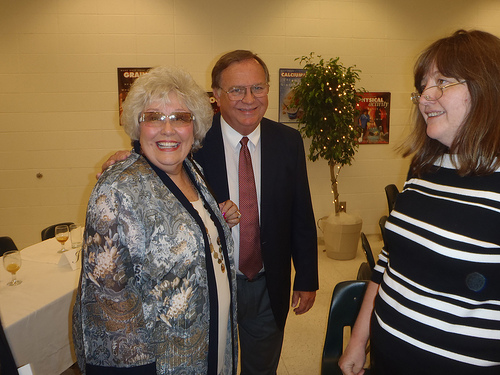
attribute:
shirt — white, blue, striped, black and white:
[361, 140, 498, 372]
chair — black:
[321, 279, 375, 373]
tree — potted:
[290, 45, 408, 291]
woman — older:
[72, 68, 244, 371]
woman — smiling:
[101, 66, 297, 309]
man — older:
[94, 49, 318, 374]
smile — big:
[234, 105, 259, 112]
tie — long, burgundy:
[233, 133, 268, 292]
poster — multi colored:
[277, 67, 309, 122]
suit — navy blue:
[209, 111, 359, 356]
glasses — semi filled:
[0, 221, 91, 291]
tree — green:
[287, 55, 374, 213]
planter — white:
[317, 213, 362, 263]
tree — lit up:
[281, 49, 372, 214]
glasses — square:
[138, 110, 193, 130]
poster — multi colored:
[352, 87, 392, 146]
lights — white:
[307, 63, 364, 211]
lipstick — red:
[154, 137, 179, 151]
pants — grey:
[233, 268, 283, 373]